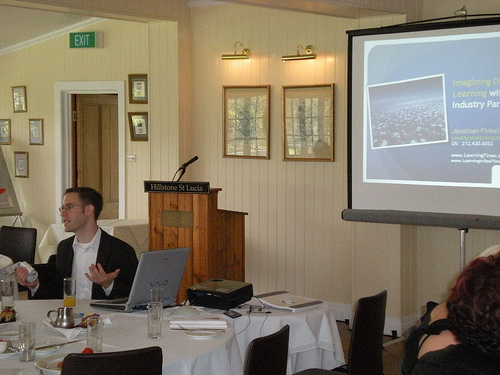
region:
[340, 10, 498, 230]
the screen is on.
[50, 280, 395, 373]
chairs at the table.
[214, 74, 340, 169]
pictures on the wall.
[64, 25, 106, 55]
exit sign is green.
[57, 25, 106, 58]
sign is above the door.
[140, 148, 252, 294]
the podium is brown.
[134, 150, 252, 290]
the podium is wooden.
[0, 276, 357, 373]
the table is white.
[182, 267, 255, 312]
the projector is black.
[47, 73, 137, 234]
the doorframe is white.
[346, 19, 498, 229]
large projection screen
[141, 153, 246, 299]
microphone attached to podium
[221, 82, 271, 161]
picture hanging on wall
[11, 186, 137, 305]
man sitting at table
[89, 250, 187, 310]
grey laptop sitting on table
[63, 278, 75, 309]
glass with orange juice inside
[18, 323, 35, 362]
empty glass on table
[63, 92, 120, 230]
brown wooden door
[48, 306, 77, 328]
silver cream serving pitcher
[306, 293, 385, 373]
black dining room chair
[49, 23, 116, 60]
a green exit sign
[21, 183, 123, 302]
a man wearing glasses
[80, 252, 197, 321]
a laptop on the table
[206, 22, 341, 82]
two light fixtures attached to the wall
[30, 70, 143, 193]
a white door frame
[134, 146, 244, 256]
a podium with a microphone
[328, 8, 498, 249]
a portable movie screen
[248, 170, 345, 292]
yellow paneling on the walls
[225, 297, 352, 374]
white table cloths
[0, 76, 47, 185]
a group of four pictures on the wall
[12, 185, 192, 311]
a man sitting at a table with laptop computer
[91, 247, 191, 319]
a man's laptop computer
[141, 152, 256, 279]
a speaker's podium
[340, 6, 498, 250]
a projector screen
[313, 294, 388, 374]
a banquet chair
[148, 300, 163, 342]
a drinking glass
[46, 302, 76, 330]
a creamer cup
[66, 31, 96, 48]
an exit sign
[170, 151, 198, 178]
a microphone on a podium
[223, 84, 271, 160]
a plaque on a wall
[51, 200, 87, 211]
EYE GLASSES ON MAN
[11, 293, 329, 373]
WHITE TABLE CLOTH ON TABLE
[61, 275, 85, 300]
HALF FULL GLASS OF ORANGE JUICE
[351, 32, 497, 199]
PROJECTOR WITH IMAGE ON IT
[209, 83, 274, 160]
PICTURE FRAME WITH GLASS ON WALL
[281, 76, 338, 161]
PICTURE FRAME WITH GLASS ON WALL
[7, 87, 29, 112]
PICTURE FRAME WITH GLASS ON WALL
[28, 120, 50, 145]
PICTURE FRAME WITH GLASS ON WALL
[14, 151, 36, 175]
PICTURE FRAME WITH GLASS ON WALL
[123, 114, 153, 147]
PICTURE FRAME WITH GLASS ON WALL